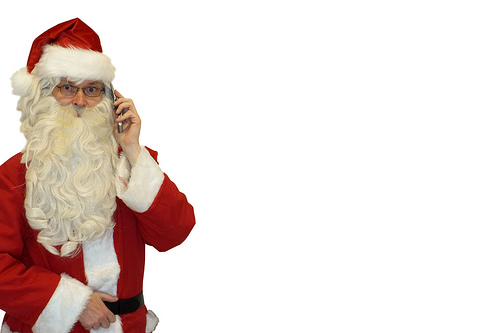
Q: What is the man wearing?
A: Santa suit.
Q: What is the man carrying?
A: Cell phone.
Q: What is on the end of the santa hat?
A: White ball.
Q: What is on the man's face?
A: Beard.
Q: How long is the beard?
A: Middle of chest.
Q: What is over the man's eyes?
A: Eyeglasses.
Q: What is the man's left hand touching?
A: Black belt.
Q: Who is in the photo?
A: Santa.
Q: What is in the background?
A: Nothing.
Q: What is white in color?
A: The background.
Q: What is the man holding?
A: A phone.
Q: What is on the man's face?
A: A beard.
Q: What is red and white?
A: The costume.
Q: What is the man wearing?
A: Glasses.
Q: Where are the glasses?
A: On the man's face.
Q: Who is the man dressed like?
A: Santa Clause.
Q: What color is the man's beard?
A: White.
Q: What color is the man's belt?
A: Black.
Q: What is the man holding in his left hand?
A: Phone.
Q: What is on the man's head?
A: Hat.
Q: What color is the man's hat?
A: Red and white.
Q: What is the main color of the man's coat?
A: Red.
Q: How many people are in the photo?
A: One.